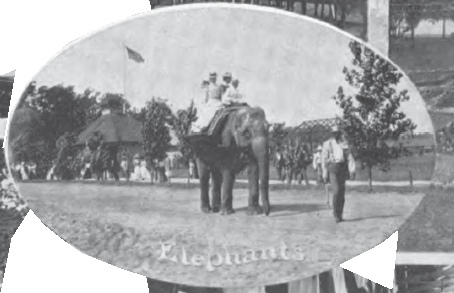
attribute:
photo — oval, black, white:
[22, 39, 448, 274]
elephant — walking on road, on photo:
[182, 116, 267, 206]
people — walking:
[194, 73, 253, 103]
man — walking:
[310, 128, 358, 212]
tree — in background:
[354, 44, 406, 193]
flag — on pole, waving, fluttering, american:
[116, 45, 154, 67]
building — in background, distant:
[77, 109, 178, 189]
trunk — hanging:
[252, 133, 271, 216]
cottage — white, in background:
[84, 130, 148, 182]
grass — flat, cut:
[113, 212, 168, 229]